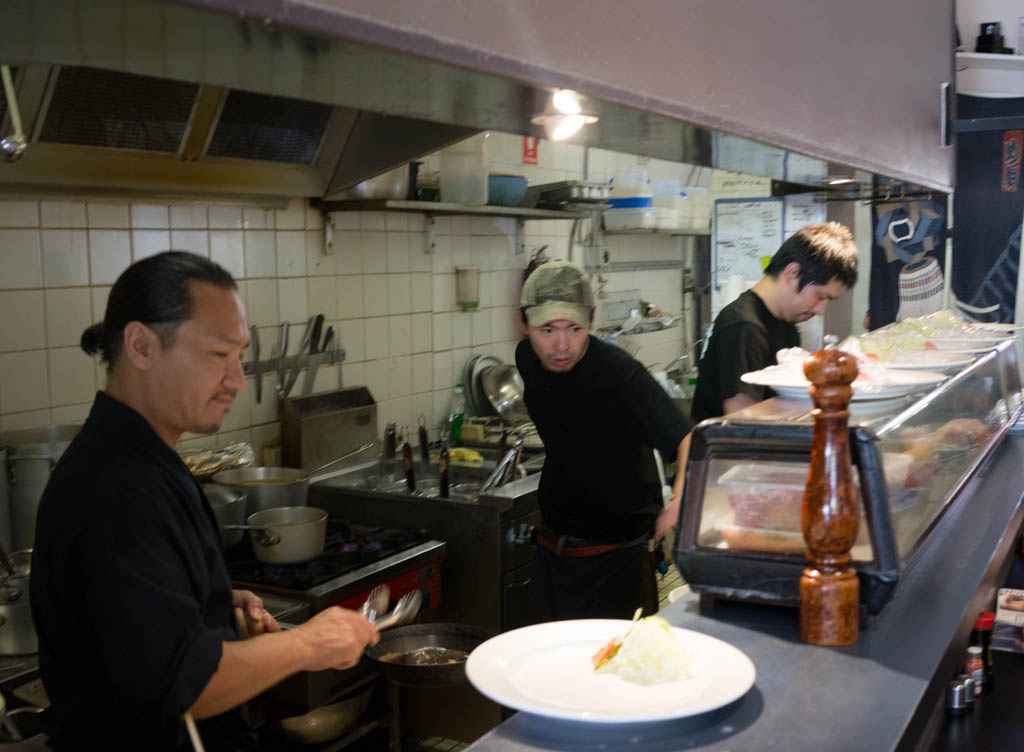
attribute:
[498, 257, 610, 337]
baseball cap — green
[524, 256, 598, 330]
baseball cap — green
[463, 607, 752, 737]
plate — large, white